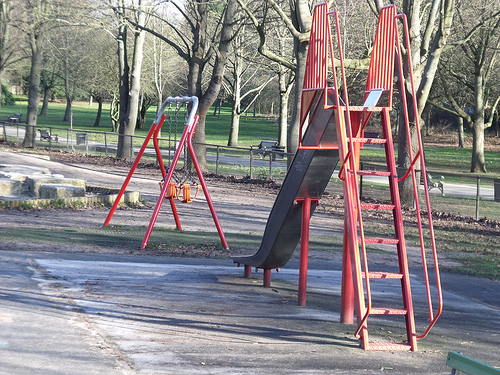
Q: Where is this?
A: This is at the park.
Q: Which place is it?
A: It is a park.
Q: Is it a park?
A: Yes, it is a park.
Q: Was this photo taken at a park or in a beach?
A: It was taken at a park.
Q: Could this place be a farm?
A: No, it is a park.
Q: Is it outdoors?
A: Yes, it is outdoors.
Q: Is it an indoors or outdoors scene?
A: It is outdoors.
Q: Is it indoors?
A: No, it is outdoors.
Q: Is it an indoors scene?
A: No, it is outdoors.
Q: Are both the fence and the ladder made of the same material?
A: Yes, both the fence and the ladder are made of metal.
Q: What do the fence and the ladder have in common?
A: The material, both the fence and the ladder are metallic.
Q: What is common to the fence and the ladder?
A: The material, both the fence and the ladder are metallic.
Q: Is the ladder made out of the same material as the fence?
A: Yes, both the ladder and the fence are made of metal.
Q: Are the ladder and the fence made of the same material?
A: Yes, both the ladder and the fence are made of metal.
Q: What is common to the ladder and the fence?
A: The material, both the ladder and the fence are metallic.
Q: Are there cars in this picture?
A: No, there are no cars.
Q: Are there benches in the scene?
A: Yes, there is a bench.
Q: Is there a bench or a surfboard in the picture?
A: Yes, there is a bench.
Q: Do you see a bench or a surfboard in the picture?
A: Yes, there is a bench.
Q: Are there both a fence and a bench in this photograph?
A: Yes, there are both a bench and a fence.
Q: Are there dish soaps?
A: No, there are no dish soaps.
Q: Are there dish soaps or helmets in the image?
A: No, there are no dish soaps or helmets.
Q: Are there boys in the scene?
A: No, there are no boys.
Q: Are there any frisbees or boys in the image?
A: No, there are no boys or frisbees.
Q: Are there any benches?
A: Yes, there is a bench.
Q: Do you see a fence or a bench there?
A: Yes, there is a bench.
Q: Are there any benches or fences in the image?
A: Yes, there is a bench.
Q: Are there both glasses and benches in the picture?
A: No, there is a bench but no glasses.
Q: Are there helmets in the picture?
A: No, there are no helmets.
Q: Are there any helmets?
A: No, there are no helmets.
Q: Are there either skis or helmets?
A: No, there are no helmets or skis.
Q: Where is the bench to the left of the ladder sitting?
A: The bench is sitting in the park.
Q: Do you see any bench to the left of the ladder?
A: Yes, there is a bench to the left of the ladder.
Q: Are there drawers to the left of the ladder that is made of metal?
A: No, there is a bench to the left of the ladder.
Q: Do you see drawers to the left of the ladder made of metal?
A: No, there is a bench to the left of the ladder.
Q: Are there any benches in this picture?
A: Yes, there is a bench.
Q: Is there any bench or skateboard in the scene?
A: Yes, there is a bench.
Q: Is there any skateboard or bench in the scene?
A: Yes, there is a bench.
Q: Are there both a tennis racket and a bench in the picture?
A: No, there is a bench but no rackets.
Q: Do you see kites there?
A: No, there are no kites.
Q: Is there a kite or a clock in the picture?
A: No, there are no kites or clocks.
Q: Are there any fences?
A: Yes, there is a fence.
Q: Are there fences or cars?
A: Yes, there is a fence.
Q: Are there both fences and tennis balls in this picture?
A: No, there is a fence but no tennis balls.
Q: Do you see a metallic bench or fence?
A: Yes, there is a metal fence.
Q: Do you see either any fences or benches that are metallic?
A: Yes, the fence is metallic.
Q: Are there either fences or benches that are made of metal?
A: Yes, the fence is made of metal.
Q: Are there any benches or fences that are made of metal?
A: Yes, the fence is made of metal.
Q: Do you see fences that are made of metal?
A: Yes, there is a fence that is made of metal.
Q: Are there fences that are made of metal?
A: Yes, there is a fence that is made of metal.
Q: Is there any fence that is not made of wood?
A: Yes, there is a fence that is made of metal.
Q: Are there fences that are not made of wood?
A: Yes, there is a fence that is made of metal.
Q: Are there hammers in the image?
A: No, there are no hammers.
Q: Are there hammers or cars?
A: No, there are no hammers or cars.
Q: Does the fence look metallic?
A: Yes, the fence is metallic.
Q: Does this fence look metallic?
A: Yes, the fence is metallic.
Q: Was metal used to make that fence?
A: Yes, the fence is made of metal.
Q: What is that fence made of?
A: The fence is made of metal.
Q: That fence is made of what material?
A: The fence is made of metal.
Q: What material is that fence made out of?
A: The fence is made of metal.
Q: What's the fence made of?
A: The fence is made of metal.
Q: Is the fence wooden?
A: No, the fence is metallic.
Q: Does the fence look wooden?
A: No, the fence is metallic.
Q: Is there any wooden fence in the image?
A: No, there is a fence but it is metallic.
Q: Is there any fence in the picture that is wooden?
A: No, there is a fence but it is metallic.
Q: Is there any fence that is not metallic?
A: No, there is a fence but it is metallic.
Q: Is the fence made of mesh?
A: No, the fence is made of metal.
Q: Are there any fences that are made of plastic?
A: No, there is a fence but it is made of metal.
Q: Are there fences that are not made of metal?
A: No, there is a fence but it is made of metal.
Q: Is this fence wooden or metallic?
A: The fence is metallic.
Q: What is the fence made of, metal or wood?
A: The fence is made of metal.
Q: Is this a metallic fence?
A: Yes, this is a metallic fence.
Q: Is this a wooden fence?
A: No, this is a metallic fence.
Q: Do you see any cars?
A: No, there are no cars.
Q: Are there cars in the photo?
A: No, there are no cars.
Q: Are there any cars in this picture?
A: No, there are no cars.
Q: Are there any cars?
A: No, there are no cars.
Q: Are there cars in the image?
A: No, there are no cars.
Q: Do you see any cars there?
A: No, there are no cars.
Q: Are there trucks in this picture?
A: No, there are no trucks.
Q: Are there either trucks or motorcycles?
A: No, there are no trucks or motorcycles.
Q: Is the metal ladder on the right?
A: Yes, the ladder is on the right of the image.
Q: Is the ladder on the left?
A: No, the ladder is on the right of the image.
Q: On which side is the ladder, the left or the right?
A: The ladder is on the right of the image.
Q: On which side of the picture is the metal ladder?
A: The ladder is on the right of the image.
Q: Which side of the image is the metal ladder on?
A: The ladder is on the right of the image.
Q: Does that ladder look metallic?
A: Yes, the ladder is metallic.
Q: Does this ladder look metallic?
A: Yes, the ladder is metallic.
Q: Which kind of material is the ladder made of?
A: The ladder is made of metal.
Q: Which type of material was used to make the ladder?
A: The ladder is made of metal.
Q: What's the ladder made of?
A: The ladder is made of metal.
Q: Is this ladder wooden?
A: No, the ladder is metallic.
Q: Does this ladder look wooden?
A: No, the ladder is metallic.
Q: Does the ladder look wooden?
A: No, the ladder is metallic.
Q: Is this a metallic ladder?
A: Yes, this is a metallic ladder.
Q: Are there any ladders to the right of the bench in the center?
A: Yes, there is a ladder to the right of the bench.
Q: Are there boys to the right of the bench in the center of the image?
A: No, there is a ladder to the right of the bench.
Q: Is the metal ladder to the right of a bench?
A: Yes, the ladder is to the right of a bench.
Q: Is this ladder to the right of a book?
A: No, the ladder is to the right of a bench.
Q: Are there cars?
A: No, there are no cars.